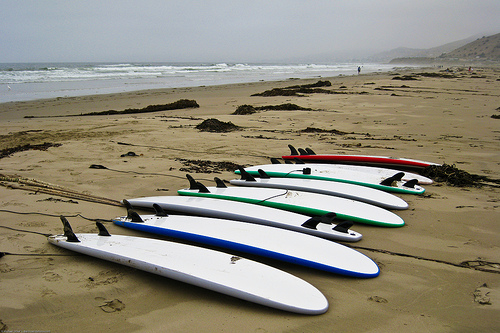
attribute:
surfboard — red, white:
[284, 143, 452, 168]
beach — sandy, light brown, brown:
[1, 68, 499, 330]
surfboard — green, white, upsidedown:
[236, 154, 425, 197]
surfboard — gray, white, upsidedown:
[232, 167, 409, 215]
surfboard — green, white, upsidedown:
[179, 173, 404, 235]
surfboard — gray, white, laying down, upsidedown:
[121, 188, 363, 248]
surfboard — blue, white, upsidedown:
[115, 200, 381, 288]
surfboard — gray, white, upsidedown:
[48, 216, 329, 318]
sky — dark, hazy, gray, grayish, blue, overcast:
[0, 2, 499, 61]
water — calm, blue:
[3, 62, 422, 103]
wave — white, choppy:
[0, 61, 275, 78]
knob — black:
[95, 219, 110, 236]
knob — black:
[63, 226, 80, 242]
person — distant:
[355, 66, 361, 74]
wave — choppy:
[211, 62, 349, 73]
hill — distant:
[368, 31, 499, 72]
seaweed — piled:
[198, 117, 242, 136]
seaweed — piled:
[235, 104, 256, 115]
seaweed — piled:
[21, 99, 200, 120]